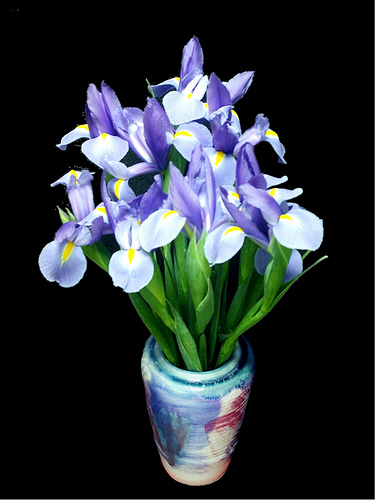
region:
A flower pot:
[130, 363, 255, 491]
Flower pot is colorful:
[140, 331, 249, 491]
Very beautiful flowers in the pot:
[34, 36, 323, 352]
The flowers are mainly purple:
[36, 34, 321, 350]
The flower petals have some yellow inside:
[33, 31, 318, 346]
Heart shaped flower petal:
[152, 81, 197, 116]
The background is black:
[3, 1, 365, 487]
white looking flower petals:
[102, 210, 329, 292]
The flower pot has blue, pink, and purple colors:
[137, 332, 248, 490]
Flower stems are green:
[75, 237, 306, 370]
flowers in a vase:
[50, 105, 276, 498]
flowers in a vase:
[157, 184, 291, 497]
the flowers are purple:
[77, 145, 286, 299]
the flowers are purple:
[76, 197, 293, 268]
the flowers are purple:
[204, 168, 314, 298]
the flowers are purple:
[139, 51, 321, 179]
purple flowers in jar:
[37, 36, 330, 492]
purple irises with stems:
[29, 41, 330, 375]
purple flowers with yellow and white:
[38, 35, 322, 291]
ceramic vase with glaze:
[128, 331, 252, 490]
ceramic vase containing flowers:
[34, 37, 330, 488]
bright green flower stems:
[50, 203, 320, 369]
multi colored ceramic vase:
[140, 328, 254, 490]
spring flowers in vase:
[36, 38, 332, 487]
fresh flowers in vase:
[40, 37, 329, 487]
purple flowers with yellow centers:
[34, 35, 332, 369]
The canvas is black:
[13, 314, 119, 488]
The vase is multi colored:
[141, 344, 257, 489]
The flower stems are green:
[99, 270, 298, 349]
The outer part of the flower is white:
[110, 262, 153, 292]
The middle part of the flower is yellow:
[126, 247, 136, 265]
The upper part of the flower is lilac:
[166, 160, 205, 231]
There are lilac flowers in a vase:
[36, 34, 329, 488]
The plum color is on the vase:
[204, 408, 240, 440]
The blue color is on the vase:
[167, 369, 235, 396]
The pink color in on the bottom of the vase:
[167, 468, 227, 485]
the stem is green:
[167, 254, 214, 359]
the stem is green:
[210, 252, 246, 351]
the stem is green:
[186, 258, 222, 368]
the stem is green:
[171, 257, 239, 398]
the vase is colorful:
[134, 328, 262, 493]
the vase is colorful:
[134, 327, 211, 465]